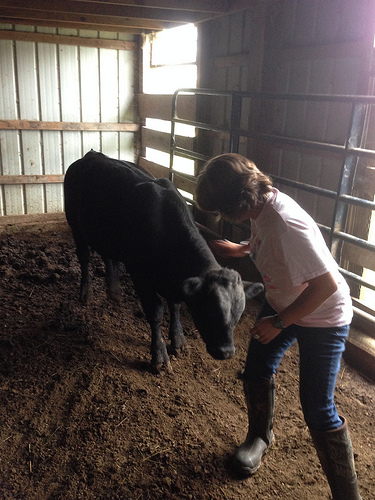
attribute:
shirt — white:
[236, 205, 365, 353]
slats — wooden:
[0, 29, 143, 225]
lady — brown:
[191, 151, 365, 498]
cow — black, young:
[58, 146, 264, 375]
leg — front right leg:
[147, 288, 174, 371]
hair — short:
[192, 149, 273, 218]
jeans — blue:
[243, 298, 349, 434]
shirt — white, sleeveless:
[239, 185, 355, 329]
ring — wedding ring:
[252, 331, 261, 340]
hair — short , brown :
[201, 151, 274, 216]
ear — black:
[176, 269, 207, 304]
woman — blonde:
[191, 147, 373, 499]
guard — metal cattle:
[167, 81, 372, 247]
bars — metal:
[239, 65, 325, 168]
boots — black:
[238, 365, 370, 489]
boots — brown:
[240, 368, 282, 478]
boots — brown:
[317, 419, 364, 496]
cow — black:
[49, 90, 259, 407]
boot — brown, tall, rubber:
[315, 418, 366, 488]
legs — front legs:
[119, 296, 196, 389]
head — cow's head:
[180, 265, 265, 359]